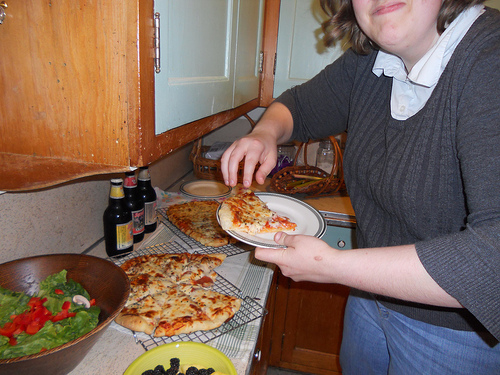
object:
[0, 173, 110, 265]
wall part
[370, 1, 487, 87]
collar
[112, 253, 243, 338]
pizza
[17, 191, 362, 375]
table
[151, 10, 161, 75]
hinge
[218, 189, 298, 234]
pizza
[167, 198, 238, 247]
pizza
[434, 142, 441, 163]
ground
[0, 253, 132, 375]
basket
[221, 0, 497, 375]
woman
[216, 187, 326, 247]
plate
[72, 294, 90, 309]
hand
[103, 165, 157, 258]
bottles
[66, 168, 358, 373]
counter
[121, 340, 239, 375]
bowl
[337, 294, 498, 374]
jeans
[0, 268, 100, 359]
salad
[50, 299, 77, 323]
mushroom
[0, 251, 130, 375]
bowl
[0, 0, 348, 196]
cabinet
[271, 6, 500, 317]
shirt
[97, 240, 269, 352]
tray